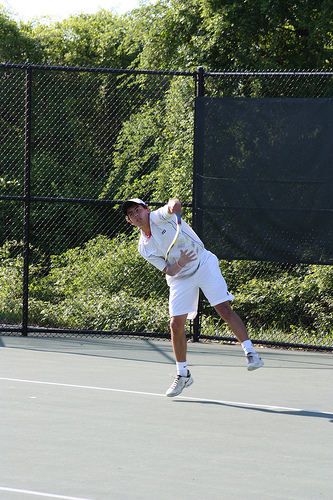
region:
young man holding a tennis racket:
[119, 198, 264, 397]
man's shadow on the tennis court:
[173, 397, 331, 423]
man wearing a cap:
[122, 199, 265, 399]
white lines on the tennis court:
[1, 377, 332, 499]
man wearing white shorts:
[121, 196, 267, 396]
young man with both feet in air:
[121, 196, 265, 397]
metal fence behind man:
[0, 63, 332, 350]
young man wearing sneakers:
[120, 198, 264, 401]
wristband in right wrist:
[174, 258, 183, 272]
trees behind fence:
[0, 0, 332, 345]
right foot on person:
[155, 368, 204, 404]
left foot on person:
[225, 336, 284, 391]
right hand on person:
[171, 244, 209, 280]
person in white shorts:
[163, 281, 241, 319]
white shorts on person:
[164, 274, 255, 320]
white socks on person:
[163, 348, 222, 383]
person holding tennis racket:
[156, 213, 254, 298]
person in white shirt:
[136, 238, 255, 293]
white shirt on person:
[137, 234, 248, 292]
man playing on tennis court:
[33, 135, 310, 439]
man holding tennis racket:
[151, 190, 215, 297]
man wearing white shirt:
[117, 210, 213, 277]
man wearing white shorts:
[150, 239, 247, 334]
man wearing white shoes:
[165, 353, 272, 400]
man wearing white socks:
[166, 352, 199, 376]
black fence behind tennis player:
[9, 46, 321, 437]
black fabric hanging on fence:
[140, 80, 332, 298]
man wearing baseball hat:
[111, 193, 148, 213]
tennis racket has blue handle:
[169, 206, 188, 241]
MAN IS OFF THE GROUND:
[121, 194, 276, 397]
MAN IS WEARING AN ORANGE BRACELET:
[174, 257, 186, 271]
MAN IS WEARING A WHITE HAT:
[119, 197, 150, 214]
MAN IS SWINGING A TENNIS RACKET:
[163, 204, 205, 281]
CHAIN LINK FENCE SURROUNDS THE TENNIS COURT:
[10, 169, 129, 324]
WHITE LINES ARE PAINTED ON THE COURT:
[12, 373, 319, 431]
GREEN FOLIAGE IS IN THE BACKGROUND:
[45, 227, 136, 308]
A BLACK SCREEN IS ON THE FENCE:
[210, 106, 327, 250]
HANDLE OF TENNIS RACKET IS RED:
[171, 203, 186, 230]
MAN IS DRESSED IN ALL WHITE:
[119, 195, 273, 393]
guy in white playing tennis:
[123, 196, 262, 396]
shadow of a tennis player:
[173, 398, 332, 421]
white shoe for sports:
[165, 371, 191, 396]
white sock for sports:
[176, 360, 186, 375]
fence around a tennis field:
[0, 60, 332, 351]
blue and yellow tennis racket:
[164, 210, 201, 278]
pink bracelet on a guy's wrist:
[175, 260, 181, 267]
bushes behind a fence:
[1, 226, 332, 343]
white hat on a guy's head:
[122, 198, 145, 214]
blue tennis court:
[1, 333, 331, 499]